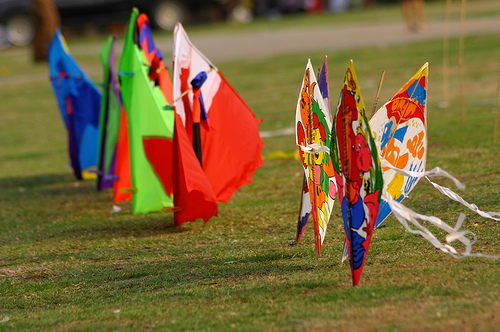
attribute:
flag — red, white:
[171, 19, 267, 228]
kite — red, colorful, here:
[330, 60, 385, 287]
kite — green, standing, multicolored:
[117, 8, 176, 215]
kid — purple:
[301, 70, 330, 210]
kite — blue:
[47, 28, 102, 180]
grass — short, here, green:
[1, 84, 499, 331]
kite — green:
[294, 59, 338, 252]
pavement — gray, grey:
[186, 17, 499, 67]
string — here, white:
[379, 190, 472, 257]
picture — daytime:
[0, 1, 499, 331]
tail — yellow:
[262, 151, 299, 162]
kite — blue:
[369, 61, 429, 234]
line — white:
[260, 124, 295, 140]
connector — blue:
[320, 56, 331, 99]